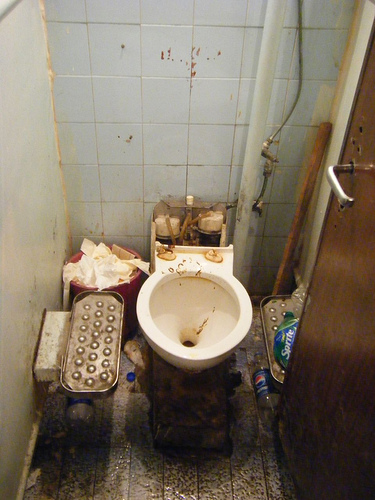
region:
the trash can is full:
[59, 240, 137, 296]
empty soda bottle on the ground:
[250, 349, 280, 428]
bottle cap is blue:
[125, 370, 137, 386]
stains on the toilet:
[192, 308, 215, 334]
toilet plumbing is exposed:
[152, 198, 228, 249]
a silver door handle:
[325, 161, 355, 206]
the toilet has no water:
[133, 264, 251, 370]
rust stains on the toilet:
[155, 247, 178, 263]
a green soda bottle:
[275, 309, 300, 368]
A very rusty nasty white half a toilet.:
[134, 206, 251, 372]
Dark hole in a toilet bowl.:
[181, 332, 197, 346]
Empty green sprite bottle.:
[274, 309, 300, 370]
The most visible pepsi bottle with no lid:
[252, 350, 284, 428]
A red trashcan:
[65, 245, 142, 336]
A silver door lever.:
[327, 162, 357, 208]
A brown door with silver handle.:
[269, 22, 373, 499]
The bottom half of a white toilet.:
[137, 239, 252, 375]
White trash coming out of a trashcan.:
[65, 237, 149, 287]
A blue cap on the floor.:
[126, 372, 135, 382]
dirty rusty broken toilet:
[140, 195, 251, 370]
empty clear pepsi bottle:
[254, 353, 281, 423]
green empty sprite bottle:
[273, 309, 303, 366]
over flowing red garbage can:
[62, 238, 147, 333]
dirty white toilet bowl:
[136, 257, 251, 369]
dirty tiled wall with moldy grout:
[45, 1, 351, 289]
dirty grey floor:
[22, 310, 295, 498]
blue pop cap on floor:
[125, 371, 134, 381]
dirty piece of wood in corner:
[271, 121, 333, 301]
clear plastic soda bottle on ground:
[241, 350, 285, 436]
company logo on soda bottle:
[245, 370, 271, 392]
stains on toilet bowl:
[179, 297, 222, 332]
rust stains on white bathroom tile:
[145, 32, 225, 90]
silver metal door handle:
[320, 156, 362, 226]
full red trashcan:
[53, 231, 144, 305]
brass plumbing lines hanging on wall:
[243, 0, 312, 221]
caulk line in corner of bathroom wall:
[31, 3, 81, 247]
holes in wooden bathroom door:
[342, 117, 373, 158]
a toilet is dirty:
[132, 191, 255, 382]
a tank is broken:
[146, 186, 239, 257]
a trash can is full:
[63, 235, 149, 300]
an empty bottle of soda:
[262, 268, 310, 382]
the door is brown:
[265, 15, 373, 498]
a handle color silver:
[325, 153, 360, 211]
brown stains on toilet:
[146, 255, 236, 291]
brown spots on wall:
[93, 9, 251, 159]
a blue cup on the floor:
[123, 367, 139, 387]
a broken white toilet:
[137, 190, 258, 382]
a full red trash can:
[56, 238, 142, 338]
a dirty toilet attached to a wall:
[138, 191, 262, 381]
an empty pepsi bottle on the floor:
[240, 339, 281, 427]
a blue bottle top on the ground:
[117, 367, 145, 387]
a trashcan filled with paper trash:
[54, 234, 152, 334]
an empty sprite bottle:
[264, 310, 320, 377]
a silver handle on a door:
[316, 148, 362, 228]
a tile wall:
[49, 0, 302, 237]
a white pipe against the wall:
[217, 2, 308, 295]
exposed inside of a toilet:
[142, 188, 237, 253]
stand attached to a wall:
[9, 287, 132, 403]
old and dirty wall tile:
[35, 17, 101, 82]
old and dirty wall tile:
[80, 14, 151, 93]